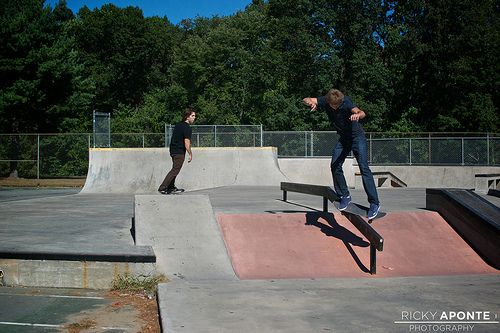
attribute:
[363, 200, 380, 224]
shoe — blue, white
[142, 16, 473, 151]
trees — tall, thick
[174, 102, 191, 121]
hair — short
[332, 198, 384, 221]
skateboard — black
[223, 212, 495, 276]
red paint — faded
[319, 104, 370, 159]
shirt — black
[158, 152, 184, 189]
pants — brown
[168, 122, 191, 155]
shirt — black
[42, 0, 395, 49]
sky — clear, blue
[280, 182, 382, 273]
railing — black